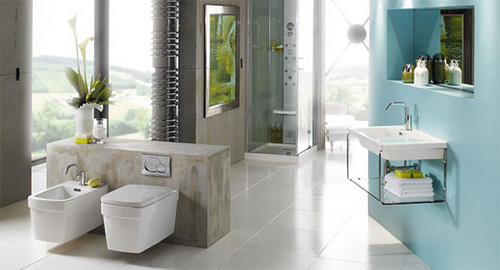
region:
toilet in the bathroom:
[95, 184, 210, 264]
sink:
[340, 104, 450, 211]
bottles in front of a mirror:
[396, 48, 466, 96]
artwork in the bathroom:
[192, 3, 253, 119]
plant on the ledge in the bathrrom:
[55, 19, 117, 150]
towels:
[385, 166, 433, 203]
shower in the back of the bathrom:
[245, 10, 311, 157]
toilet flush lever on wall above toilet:
[140, 153, 181, 178]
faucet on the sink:
[370, 90, 415, 130]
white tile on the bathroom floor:
[250, 176, 338, 244]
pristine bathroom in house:
[8, 2, 479, 263]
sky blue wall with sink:
[458, 165, 488, 231]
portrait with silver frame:
[198, 1, 246, 123]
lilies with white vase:
[63, 5, 100, 138]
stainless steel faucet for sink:
[378, 95, 418, 127]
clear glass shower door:
[248, 15, 280, 146]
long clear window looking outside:
[36, 29, 68, 129]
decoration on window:
[325, 10, 367, 80]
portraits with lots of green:
[207, 15, 239, 107]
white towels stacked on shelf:
[391, 166, 436, 200]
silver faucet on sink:
[387, 99, 418, 131]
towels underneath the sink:
[392, 179, 424, 194]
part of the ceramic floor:
[269, 193, 342, 241]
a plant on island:
[66, 25, 99, 145]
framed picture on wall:
[204, 5, 246, 113]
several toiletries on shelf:
[407, 52, 466, 92]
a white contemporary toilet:
[101, 181, 181, 256]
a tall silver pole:
[155, 0, 180, 137]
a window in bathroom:
[332, 34, 362, 111]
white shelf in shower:
[274, 96, 291, 118]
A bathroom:
[5, 1, 478, 268]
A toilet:
[102, 150, 184, 258]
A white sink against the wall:
[342, 102, 451, 207]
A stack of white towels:
[383, 171, 438, 207]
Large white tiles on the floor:
[236, 168, 342, 261]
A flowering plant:
[56, 14, 117, 142]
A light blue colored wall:
[367, 0, 496, 268]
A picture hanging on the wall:
[204, 4, 246, 121]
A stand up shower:
[249, 3, 323, 163]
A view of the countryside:
[29, 46, 161, 167]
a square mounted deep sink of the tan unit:
[25, 181, 106, 244]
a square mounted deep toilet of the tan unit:
[102, 183, 181, 256]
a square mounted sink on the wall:
[341, 124, 453, 206]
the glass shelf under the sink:
[349, 169, 443, 206]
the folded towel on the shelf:
[381, 169, 433, 186]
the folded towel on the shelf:
[383, 186, 435, 199]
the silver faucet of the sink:
[62, 160, 81, 182]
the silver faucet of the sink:
[383, 101, 411, 128]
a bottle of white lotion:
[419, 58, 430, 86]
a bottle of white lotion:
[412, 58, 421, 86]